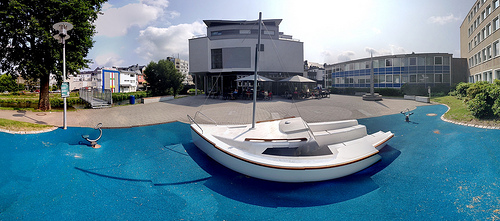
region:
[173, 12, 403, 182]
a boat is in the pool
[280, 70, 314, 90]
the tent is white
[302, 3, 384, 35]
the sun is bright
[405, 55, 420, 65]
the building has a window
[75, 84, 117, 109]
the bridge is small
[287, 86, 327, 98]
the people are sitting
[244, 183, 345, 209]
the shadow is on the bottom of the pool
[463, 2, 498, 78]
the building is tan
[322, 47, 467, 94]
the building is wide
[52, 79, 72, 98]
the sign is on the pole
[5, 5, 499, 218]
Boat sitting in the water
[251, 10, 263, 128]
Metal mast on front of boat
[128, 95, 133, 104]
Blue garbage can with lid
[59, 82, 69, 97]
Green sign on metal pole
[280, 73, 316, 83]
Large umbrella next to building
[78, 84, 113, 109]
Metal walkway with fence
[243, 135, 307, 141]
Red railing on boat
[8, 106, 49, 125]
Group of shadows on the pavement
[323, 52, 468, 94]
Blue and grey building in the background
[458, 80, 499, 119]
Green bush next to building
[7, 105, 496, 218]
a boat in a body of water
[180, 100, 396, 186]
boat is color white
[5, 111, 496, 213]
the water is color blue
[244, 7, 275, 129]
the mast of a boat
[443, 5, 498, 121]
plants in front a building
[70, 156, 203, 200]
a reflection of a pole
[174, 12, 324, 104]
a white building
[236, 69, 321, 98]
parasol in front a building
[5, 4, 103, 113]
a green tree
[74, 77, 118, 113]
a bridge over a creek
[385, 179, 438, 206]
the water is blue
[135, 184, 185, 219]
the water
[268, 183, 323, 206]
shadow in the water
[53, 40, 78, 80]
a pole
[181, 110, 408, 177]
a boat in the water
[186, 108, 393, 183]
the boat is white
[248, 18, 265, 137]
a pole on the boat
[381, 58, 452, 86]
a building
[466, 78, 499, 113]
the tree bush is green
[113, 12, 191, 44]
clouds in the sky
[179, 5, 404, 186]
White and brown sailboat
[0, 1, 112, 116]
Lush, green tree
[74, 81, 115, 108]
Silver walking bridge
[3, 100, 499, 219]
Crystal clear blue water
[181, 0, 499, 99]
Gray, white, and brown buildings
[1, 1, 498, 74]
Sunny sky with puffy white clouds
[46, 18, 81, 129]
Silver lamp post with sign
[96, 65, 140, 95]
White red and blue building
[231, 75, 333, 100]
Outside seating with umbrellas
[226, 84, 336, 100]
People sitting and standing outside